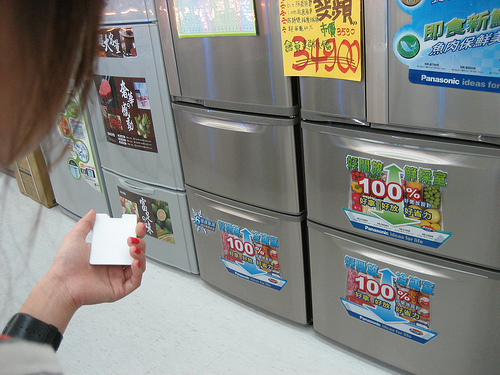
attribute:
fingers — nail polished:
[124, 240, 148, 300]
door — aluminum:
[296, 120, 500, 263]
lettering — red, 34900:
[285, 33, 360, 79]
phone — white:
[86, 201, 141, 271]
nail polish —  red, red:
[132, 230, 145, 269]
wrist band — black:
[2, 307, 70, 350]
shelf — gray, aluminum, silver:
[155, 0, 499, 375]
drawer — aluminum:
[183, 184, 313, 329]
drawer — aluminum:
[307, 220, 498, 375]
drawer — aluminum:
[155, 5, 300, 118]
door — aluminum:
[85, 22, 198, 279]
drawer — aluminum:
[174, 99, 305, 214]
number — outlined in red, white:
[358, 174, 408, 201]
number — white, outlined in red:
[351, 274, 399, 303]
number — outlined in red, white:
[225, 233, 256, 257]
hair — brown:
[2, 1, 115, 243]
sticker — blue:
[388, 4, 496, 97]